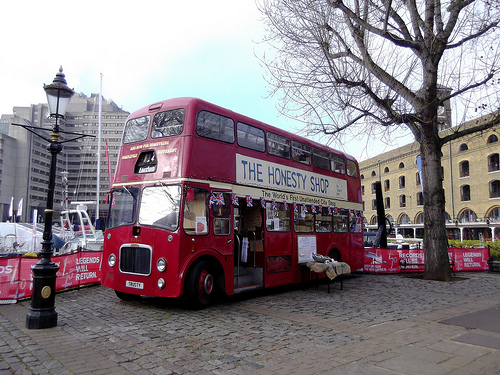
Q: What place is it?
A: It is a street.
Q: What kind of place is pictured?
A: It is a street.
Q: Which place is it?
A: It is a street.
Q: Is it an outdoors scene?
A: Yes, it is outdoors.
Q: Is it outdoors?
A: Yes, it is outdoors.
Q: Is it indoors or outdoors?
A: It is outdoors.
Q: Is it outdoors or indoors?
A: It is outdoors.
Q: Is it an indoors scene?
A: No, it is outdoors.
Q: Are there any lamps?
A: Yes, there is a lamp.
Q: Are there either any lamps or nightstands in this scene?
A: Yes, there is a lamp.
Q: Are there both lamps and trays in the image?
A: No, there is a lamp but no trays.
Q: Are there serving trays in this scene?
A: No, there are no serving trays.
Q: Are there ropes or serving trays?
A: No, there are no serving trays or ropes.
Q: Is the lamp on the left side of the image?
A: Yes, the lamp is on the left of the image.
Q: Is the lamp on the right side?
A: No, the lamp is on the left of the image.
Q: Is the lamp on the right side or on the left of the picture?
A: The lamp is on the left of the image.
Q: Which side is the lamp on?
A: The lamp is on the left of the image.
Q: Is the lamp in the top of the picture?
A: Yes, the lamp is in the top of the image.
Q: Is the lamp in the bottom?
A: No, the lamp is in the top of the image.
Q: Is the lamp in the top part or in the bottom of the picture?
A: The lamp is in the top of the image.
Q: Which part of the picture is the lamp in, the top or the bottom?
A: The lamp is in the top of the image.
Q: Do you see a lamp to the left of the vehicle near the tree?
A: Yes, there is a lamp to the left of the bus.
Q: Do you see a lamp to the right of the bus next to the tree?
A: No, the lamp is to the left of the bus.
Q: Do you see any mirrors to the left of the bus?
A: No, there is a lamp to the left of the bus.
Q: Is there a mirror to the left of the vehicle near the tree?
A: No, there is a lamp to the left of the bus.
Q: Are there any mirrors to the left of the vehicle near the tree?
A: No, there is a lamp to the left of the bus.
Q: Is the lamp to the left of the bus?
A: Yes, the lamp is to the left of the bus.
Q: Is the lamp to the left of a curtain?
A: No, the lamp is to the left of the bus.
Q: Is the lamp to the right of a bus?
A: No, the lamp is to the left of a bus.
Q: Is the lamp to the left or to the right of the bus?
A: The lamp is to the left of the bus.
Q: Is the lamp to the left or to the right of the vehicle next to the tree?
A: The lamp is to the left of the bus.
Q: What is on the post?
A: The lamp is on the post.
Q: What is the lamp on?
A: The lamp is on the post.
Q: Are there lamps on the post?
A: Yes, there is a lamp on the post.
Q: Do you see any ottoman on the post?
A: No, there is a lamp on the post.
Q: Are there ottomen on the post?
A: No, there is a lamp on the post.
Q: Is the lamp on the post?
A: Yes, the lamp is on the post.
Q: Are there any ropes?
A: No, there are no ropes.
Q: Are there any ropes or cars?
A: No, there are no ropes or cars.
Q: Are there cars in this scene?
A: No, there are no cars.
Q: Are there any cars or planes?
A: No, there are no cars or planes.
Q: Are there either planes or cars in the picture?
A: No, there are no cars or planes.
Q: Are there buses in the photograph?
A: Yes, there is a bus.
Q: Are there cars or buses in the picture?
A: Yes, there is a bus.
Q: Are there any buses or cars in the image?
A: Yes, there is a bus.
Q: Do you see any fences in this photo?
A: No, there are no fences.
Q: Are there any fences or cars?
A: No, there are no fences or cars.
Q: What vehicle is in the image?
A: The vehicle is a bus.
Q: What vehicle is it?
A: The vehicle is a bus.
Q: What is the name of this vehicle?
A: This is a bus.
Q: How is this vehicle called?
A: This is a bus.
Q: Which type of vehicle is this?
A: This is a bus.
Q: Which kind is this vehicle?
A: This is a bus.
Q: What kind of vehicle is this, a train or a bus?
A: This is a bus.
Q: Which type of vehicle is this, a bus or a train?
A: This is a bus.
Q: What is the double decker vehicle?
A: The vehicle is a bus.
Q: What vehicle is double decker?
A: The vehicle is a bus.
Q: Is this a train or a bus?
A: This is a bus.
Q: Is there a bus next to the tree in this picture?
A: Yes, there is a bus next to the tree.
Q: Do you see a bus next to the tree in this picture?
A: Yes, there is a bus next to the tree.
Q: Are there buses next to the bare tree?
A: Yes, there is a bus next to the tree.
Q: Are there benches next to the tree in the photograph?
A: No, there is a bus next to the tree.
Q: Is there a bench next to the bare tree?
A: No, there is a bus next to the tree.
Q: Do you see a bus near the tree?
A: Yes, there is a bus near the tree.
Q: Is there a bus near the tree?
A: Yes, there is a bus near the tree.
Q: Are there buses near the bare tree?
A: Yes, there is a bus near the tree.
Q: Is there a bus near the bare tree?
A: Yes, there is a bus near the tree.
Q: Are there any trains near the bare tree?
A: No, there is a bus near the tree.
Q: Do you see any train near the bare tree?
A: No, there is a bus near the tree.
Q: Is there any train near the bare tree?
A: No, there is a bus near the tree.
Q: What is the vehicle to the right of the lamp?
A: The vehicle is a bus.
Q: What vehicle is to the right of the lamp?
A: The vehicle is a bus.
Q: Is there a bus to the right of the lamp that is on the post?
A: Yes, there is a bus to the right of the lamp.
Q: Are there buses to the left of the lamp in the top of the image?
A: No, the bus is to the right of the lamp.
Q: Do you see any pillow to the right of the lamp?
A: No, there is a bus to the right of the lamp.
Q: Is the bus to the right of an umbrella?
A: No, the bus is to the right of a lamp.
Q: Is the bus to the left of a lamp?
A: No, the bus is to the right of a lamp.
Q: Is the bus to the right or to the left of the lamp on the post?
A: The bus is to the right of the lamp.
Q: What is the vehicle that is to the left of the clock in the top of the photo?
A: The vehicle is a bus.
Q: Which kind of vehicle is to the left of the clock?
A: The vehicle is a bus.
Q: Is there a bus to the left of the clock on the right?
A: Yes, there is a bus to the left of the clock.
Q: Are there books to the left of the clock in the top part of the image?
A: No, there is a bus to the left of the clock.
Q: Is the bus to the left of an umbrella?
A: No, the bus is to the left of a clock.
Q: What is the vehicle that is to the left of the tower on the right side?
A: The vehicle is a bus.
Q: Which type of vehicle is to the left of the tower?
A: The vehicle is a bus.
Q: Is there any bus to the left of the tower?
A: Yes, there is a bus to the left of the tower.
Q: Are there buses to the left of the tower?
A: Yes, there is a bus to the left of the tower.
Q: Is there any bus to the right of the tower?
A: No, the bus is to the left of the tower.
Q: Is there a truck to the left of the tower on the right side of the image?
A: No, there is a bus to the left of the tower.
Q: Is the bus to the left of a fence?
A: No, the bus is to the left of the tower.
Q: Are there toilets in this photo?
A: No, there are no toilets.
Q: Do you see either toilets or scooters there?
A: No, there are no toilets or scooters.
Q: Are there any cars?
A: No, there are no cars.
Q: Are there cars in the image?
A: No, there are no cars.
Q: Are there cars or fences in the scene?
A: No, there are no cars or fences.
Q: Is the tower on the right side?
A: Yes, the tower is on the right of the image.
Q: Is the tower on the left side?
A: No, the tower is on the right of the image.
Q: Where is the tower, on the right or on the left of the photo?
A: The tower is on the right of the image.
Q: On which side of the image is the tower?
A: The tower is on the right of the image.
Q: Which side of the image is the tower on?
A: The tower is on the right of the image.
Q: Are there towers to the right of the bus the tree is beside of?
A: Yes, there is a tower to the right of the bus.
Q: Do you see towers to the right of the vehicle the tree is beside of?
A: Yes, there is a tower to the right of the bus.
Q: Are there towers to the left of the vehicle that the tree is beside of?
A: No, the tower is to the right of the bus.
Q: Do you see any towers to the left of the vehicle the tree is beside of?
A: No, the tower is to the right of the bus.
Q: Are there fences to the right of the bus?
A: No, there is a tower to the right of the bus.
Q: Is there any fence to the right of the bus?
A: No, there is a tower to the right of the bus.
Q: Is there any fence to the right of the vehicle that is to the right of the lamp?
A: No, there is a tower to the right of the bus.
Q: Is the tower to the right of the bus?
A: Yes, the tower is to the right of the bus.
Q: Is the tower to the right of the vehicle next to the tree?
A: Yes, the tower is to the right of the bus.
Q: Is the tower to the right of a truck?
A: No, the tower is to the right of the bus.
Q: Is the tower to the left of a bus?
A: No, the tower is to the right of a bus.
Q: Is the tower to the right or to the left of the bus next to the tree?
A: The tower is to the right of the bus.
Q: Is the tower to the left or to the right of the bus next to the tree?
A: The tower is to the right of the bus.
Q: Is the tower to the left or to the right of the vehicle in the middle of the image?
A: The tower is to the right of the bus.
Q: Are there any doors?
A: Yes, there is a door.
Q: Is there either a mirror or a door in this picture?
A: Yes, there is a door.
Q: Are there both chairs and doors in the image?
A: No, there is a door but no chairs.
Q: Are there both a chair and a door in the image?
A: No, there is a door but no chairs.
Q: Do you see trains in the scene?
A: No, there are no trains.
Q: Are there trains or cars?
A: No, there are no trains or cars.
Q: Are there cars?
A: No, there are no cars.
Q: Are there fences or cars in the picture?
A: No, there are no cars or fences.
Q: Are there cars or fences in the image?
A: No, there are no cars or fences.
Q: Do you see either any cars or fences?
A: No, there are no cars or fences.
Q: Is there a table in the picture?
A: Yes, there is a table.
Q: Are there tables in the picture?
A: Yes, there is a table.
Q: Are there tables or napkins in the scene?
A: Yes, there is a table.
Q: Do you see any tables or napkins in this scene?
A: Yes, there is a table.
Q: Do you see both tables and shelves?
A: No, there is a table but no shelves.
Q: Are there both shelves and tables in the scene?
A: No, there is a table but no shelves.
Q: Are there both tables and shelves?
A: No, there is a table but no shelves.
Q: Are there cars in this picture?
A: No, there are no cars.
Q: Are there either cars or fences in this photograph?
A: No, there are no cars or fences.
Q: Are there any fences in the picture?
A: No, there are no fences.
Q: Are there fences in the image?
A: No, there are no fences.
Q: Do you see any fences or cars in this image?
A: No, there are no fences or cars.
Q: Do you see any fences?
A: No, there are no fences.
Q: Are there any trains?
A: No, there are no trains.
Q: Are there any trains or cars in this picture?
A: No, there are no trains or cars.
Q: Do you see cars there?
A: No, there are no cars.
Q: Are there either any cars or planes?
A: No, there are no cars or planes.